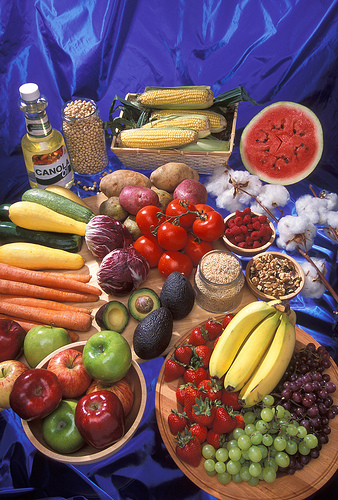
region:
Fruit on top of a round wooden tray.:
[152, 290, 334, 496]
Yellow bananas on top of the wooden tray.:
[206, 290, 291, 403]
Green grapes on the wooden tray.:
[200, 390, 317, 482]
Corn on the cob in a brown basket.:
[97, 80, 248, 168]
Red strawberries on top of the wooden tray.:
[159, 308, 245, 465]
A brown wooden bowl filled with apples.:
[10, 329, 144, 456]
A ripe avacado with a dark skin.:
[129, 303, 169, 355]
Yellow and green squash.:
[0, 184, 96, 266]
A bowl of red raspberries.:
[221, 205, 273, 249]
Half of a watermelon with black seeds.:
[239, 100, 323, 183]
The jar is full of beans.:
[59, 91, 109, 176]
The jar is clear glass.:
[58, 95, 109, 176]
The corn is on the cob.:
[131, 77, 222, 111]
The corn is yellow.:
[131, 84, 216, 105]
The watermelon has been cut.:
[244, 95, 327, 189]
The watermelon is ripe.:
[243, 99, 317, 187]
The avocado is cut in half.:
[97, 298, 133, 338]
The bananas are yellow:
[214, 301, 289, 404]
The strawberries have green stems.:
[166, 359, 219, 454]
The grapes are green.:
[227, 422, 294, 477]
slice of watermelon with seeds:
[243, 99, 322, 178]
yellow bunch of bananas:
[211, 295, 295, 407]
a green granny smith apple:
[82, 328, 130, 386]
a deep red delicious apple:
[73, 393, 126, 446]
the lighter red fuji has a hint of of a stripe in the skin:
[49, 349, 139, 408]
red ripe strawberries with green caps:
[165, 360, 242, 470]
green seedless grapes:
[207, 400, 336, 482]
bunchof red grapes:
[277, 338, 336, 438]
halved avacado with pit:
[93, 285, 170, 329]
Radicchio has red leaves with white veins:
[85, 215, 145, 289]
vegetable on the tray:
[196, 212, 224, 240]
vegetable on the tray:
[101, 254, 145, 282]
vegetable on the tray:
[104, 247, 137, 285]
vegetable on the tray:
[102, 255, 135, 290]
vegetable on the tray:
[127, 205, 162, 226]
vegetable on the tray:
[80, 216, 117, 244]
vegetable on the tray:
[4, 246, 79, 267]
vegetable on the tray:
[39, 194, 82, 221]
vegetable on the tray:
[18, 303, 95, 321]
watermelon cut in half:
[238, 98, 323, 182]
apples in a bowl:
[7, 329, 150, 476]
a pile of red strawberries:
[156, 376, 256, 473]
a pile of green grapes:
[196, 396, 313, 482]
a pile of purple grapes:
[270, 342, 336, 429]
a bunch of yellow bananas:
[204, 282, 307, 411]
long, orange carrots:
[0, 262, 102, 338]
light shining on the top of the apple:
[79, 394, 110, 417]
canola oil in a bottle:
[13, 79, 77, 197]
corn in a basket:
[102, 70, 246, 176]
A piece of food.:
[157, 244, 195, 284]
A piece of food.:
[192, 400, 218, 432]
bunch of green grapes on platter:
[200, 391, 317, 488]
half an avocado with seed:
[126, 284, 165, 324]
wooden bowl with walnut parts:
[247, 249, 307, 305]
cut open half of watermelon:
[238, 131, 322, 187]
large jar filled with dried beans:
[58, 95, 116, 179]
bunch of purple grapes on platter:
[275, 340, 333, 434]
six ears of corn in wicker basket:
[114, 81, 235, 166]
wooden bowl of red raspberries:
[221, 200, 274, 254]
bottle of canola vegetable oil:
[15, 146, 74, 189]